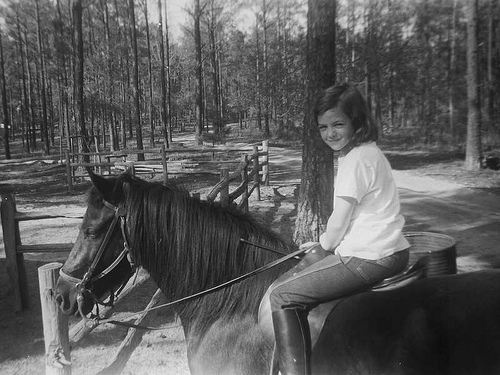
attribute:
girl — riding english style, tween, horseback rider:
[261, 77, 419, 374]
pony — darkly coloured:
[44, 157, 499, 374]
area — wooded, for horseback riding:
[2, 1, 500, 207]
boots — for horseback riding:
[265, 301, 317, 374]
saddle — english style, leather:
[242, 235, 435, 373]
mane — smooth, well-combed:
[75, 166, 305, 343]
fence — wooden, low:
[1, 136, 274, 375]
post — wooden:
[260, 138, 271, 188]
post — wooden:
[250, 144, 265, 202]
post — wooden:
[238, 150, 252, 215]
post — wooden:
[219, 166, 232, 205]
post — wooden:
[32, 257, 78, 375]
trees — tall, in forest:
[2, 1, 500, 177]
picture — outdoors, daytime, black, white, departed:
[1, 1, 499, 375]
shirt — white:
[316, 139, 415, 262]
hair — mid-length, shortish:
[311, 79, 380, 151]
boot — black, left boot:
[271, 306, 319, 375]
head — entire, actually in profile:
[47, 161, 140, 326]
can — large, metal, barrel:
[401, 228, 457, 273]